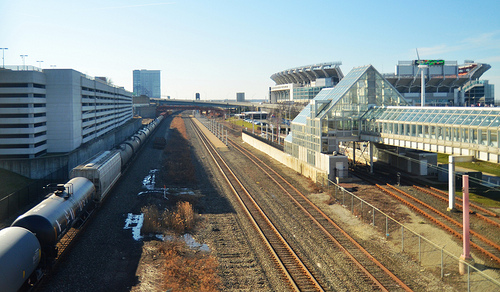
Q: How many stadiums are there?
A: One.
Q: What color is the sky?
A: Blue.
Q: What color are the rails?
A: Brown.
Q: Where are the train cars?
A: Left side.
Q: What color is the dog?
A: No dog.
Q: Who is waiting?
A: No one.